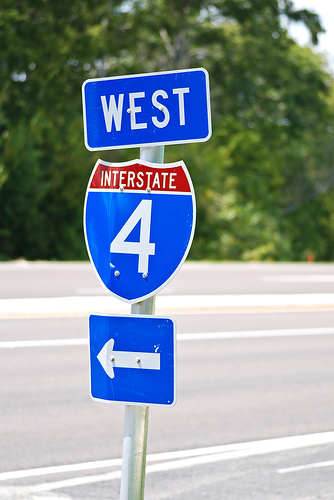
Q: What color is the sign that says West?
A: Blue.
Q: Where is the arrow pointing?
A: To the left.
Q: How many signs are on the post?
A: Three.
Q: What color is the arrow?
A: White.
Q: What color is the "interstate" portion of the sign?
A: Red.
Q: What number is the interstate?
A: 4.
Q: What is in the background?
A: Trees.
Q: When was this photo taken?
A: During the daytime.